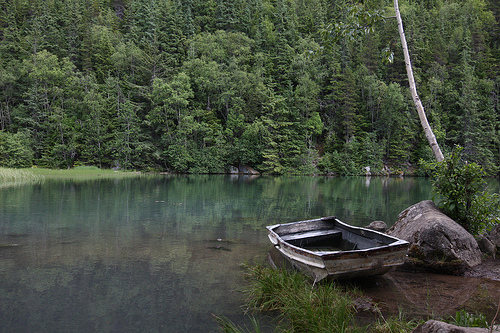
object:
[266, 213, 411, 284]
boat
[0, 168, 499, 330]
water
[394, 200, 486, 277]
rock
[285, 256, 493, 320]
shore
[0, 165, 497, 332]
river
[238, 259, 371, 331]
grass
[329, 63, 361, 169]
tree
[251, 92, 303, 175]
tree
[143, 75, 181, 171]
tree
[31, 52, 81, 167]
tree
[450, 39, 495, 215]
tree